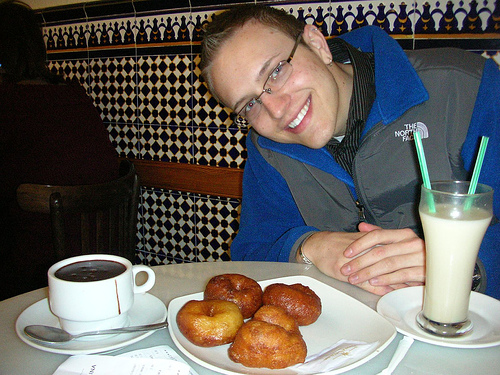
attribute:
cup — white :
[19, 260, 164, 367]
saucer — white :
[42, 232, 131, 314]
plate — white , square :
[212, 255, 399, 354]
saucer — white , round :
[4, 241, 177, 359]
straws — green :
[394, 113, 484, 229]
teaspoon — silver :
[28, 298, 187, 361]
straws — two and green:
[382, 128, 499, 292]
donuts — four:
[177, 284, 307, 375]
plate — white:
[282, 364, 358, 375]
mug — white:
[62, 272, 152, 367]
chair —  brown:
[224, 124, 497, 282]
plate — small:
[84, 308, 140, 367]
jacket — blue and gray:
[262, 118, 415, 220]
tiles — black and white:
[111, 54, 149, 114]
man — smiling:
[194, 1, 484, 305]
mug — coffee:
[36, 246, 162, 337]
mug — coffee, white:
[40, 248, 166, 339]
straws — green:
[410, 125, 484, 214]